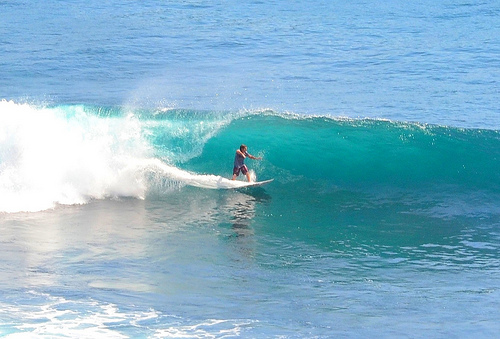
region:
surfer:
[219, 125, 263, 199]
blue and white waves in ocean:
[24, 78, 54, 112]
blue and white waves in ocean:
[369, 38, 422, 113]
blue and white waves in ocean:
[366, 105, 415, 141]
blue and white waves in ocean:
[336, 242, 358, 284]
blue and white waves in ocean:
[108, 240, 153, 282]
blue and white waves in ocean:
[352, 180, 415, 219]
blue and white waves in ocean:
[92, 221, 187, 298]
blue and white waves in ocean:
[19, 78, 96, 165]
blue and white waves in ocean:
[149, 22, 242, 79]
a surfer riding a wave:
[230, 141, 263, 183]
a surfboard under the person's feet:
[237, 177, 274, 193]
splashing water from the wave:
[0, 89, 181, 215]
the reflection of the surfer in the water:
[217, 183, 274, 260]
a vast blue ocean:
[0, 0, 498, 337]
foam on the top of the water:
[0, 288, 254, 337]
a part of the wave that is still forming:
[222, 108, 497, 195]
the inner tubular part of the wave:
[182, 115, 253, 182]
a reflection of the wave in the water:
[0, 192, 162, 288]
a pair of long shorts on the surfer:
[233, 164, 247, 176]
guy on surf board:
[203, 140, 280, 197]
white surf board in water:
[215, 173, 279, 203]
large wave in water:
[88, 118, 177, 193]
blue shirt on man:
[229, 150, 254, 170]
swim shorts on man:
[230, 163, 249, 178]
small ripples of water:
[196, 35, 228, 58]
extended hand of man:
[250, 150, 265, 165]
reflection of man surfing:
[215, 187, 264, 238]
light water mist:
[113, 81, 150, 101]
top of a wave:
[268, 105, 305, 124]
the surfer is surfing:
[206, 123, 306, 223]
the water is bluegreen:
[292, 141, 369, 205]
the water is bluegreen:
[275, 136, 380, 251]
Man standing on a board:
[212, 173, 275, 190]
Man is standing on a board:
[207, 172, 282, 193]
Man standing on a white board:
[207, 176, 277, 191]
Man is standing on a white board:
[210, 172, 275, 192]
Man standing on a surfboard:
[212, 172, 277, 194]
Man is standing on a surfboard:
[215, 170, 282, 195]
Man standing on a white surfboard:
[212, 172, 274, 191]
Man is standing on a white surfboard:
[216, 177, 283, 191]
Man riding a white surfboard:
[226, 142, 273, 192]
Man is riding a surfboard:
[219, 143, 272, 195]